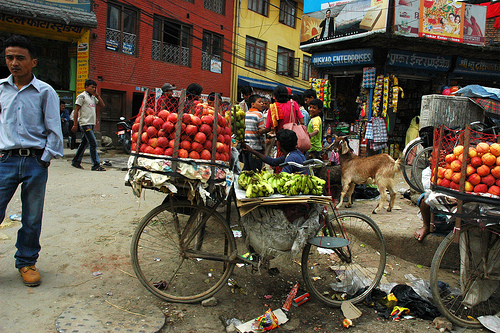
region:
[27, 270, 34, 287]
left foot of a man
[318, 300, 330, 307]
front wheel of a bicycle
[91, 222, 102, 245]
part of a path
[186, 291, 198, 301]
back wheel of a bicycle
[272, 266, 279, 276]
pedal of a bicycle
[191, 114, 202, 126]
section of tomatoes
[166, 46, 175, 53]
balcony of a house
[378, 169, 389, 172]
part of a goat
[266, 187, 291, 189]
part of bananas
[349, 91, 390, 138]
inside of a shop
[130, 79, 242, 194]
apples in a cage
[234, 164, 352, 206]
bananas sitting on cardboard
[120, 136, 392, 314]
a bike holding fruit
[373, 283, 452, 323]
a black trash bag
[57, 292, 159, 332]
a round manhole cover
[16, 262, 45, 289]
a boot on a man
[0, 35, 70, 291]
a man with black hair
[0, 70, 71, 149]
a blue shirt on a man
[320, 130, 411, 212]
a goat at the market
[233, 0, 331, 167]
a yellow building near the market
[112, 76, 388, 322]
bike with baskets on it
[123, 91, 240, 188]
basket with red fruit inside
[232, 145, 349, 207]
green bananas carried by bike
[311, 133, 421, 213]
brown dog in street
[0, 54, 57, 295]
man with hands in pockets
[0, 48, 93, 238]
man with black belt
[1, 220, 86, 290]
man with brown boots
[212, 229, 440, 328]
garbage underneath bik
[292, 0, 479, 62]
signs on top of building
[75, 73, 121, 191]
man in white shirt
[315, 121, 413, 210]
There is a goat by the stand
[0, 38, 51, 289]
Man wearing blue shirt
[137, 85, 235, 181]
There is a stack of apples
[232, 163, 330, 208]
There are a bunch of bananas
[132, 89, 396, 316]
The bike is piled with fruit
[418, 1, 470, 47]
The sign above the stand is muti-colored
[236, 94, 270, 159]
The boy is wearing a striped shirt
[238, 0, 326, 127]
The building is yellow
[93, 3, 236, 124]
The building is red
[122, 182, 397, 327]
There are tires on the bike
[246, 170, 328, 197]
yellow bananas in cart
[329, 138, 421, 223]
brown goat in marketplace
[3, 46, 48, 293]
man wearing blue jeans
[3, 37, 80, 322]
man wearing denim shirt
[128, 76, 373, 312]
fruit cart with wheels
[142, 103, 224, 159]
peaches in a cart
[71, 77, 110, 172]
man in background walking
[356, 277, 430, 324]
garbage spilled on ground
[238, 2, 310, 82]
yellow building with windows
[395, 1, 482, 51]
billboards on side of building